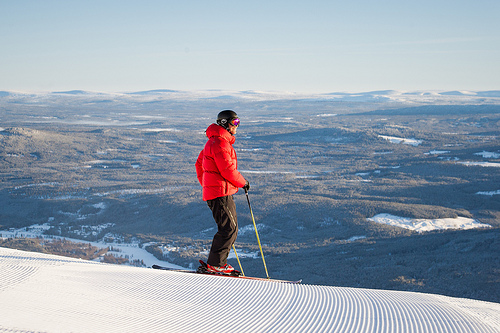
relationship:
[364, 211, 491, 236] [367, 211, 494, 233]
patch of patch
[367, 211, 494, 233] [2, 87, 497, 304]
patch on landscape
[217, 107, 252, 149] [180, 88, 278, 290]
helmet on skier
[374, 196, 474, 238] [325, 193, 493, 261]
snow covers land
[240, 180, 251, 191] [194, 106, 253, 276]
gloves on skier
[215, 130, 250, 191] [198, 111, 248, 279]
arm on person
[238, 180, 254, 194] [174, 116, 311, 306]
hand on person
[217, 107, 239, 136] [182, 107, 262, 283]
head on person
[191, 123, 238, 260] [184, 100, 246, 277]
body on person